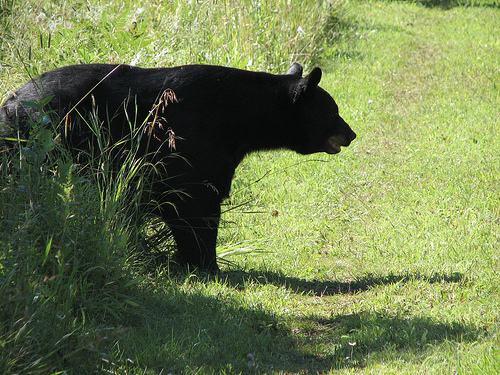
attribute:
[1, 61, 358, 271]
bear — black, in sun, showing teeth, alone, furry, curious, hairy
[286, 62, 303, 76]
ear — pointing up, perked, black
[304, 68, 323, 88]
ear — perked, pointing up, black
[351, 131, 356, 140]
nose — black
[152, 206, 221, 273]
legs — black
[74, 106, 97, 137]
grass — long, reedy, green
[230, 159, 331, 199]
grass — short, reedy, green, long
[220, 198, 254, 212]
grass — long, short, reedy, green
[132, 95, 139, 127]
grass — long, reedy, green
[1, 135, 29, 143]
grass — reedy, green, long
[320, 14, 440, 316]
track — grass, brown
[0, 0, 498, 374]
grass — sunlit, green, field, short, wispy, tall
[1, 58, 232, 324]
grass clump — long, weedy, tall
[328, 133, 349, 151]
mouth — brown